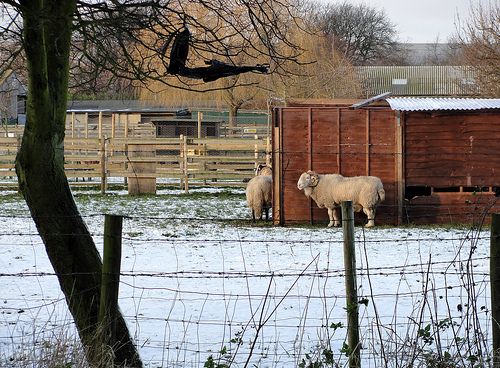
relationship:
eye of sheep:
[304, 175, 312, 180] [295, 166, 387, 229]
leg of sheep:
[360, 205, 377, 227] [295, 166, 387, 229]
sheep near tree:
[295, 166, 387, 229] [1, 0, 318, 365]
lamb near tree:
[246, 162, 277, 222] [1, 0, 318, 365]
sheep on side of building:
[295, 166, 387, 229] [275, 62, 498, 224]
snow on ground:
[0, 220, 500, 368] [4, 148, 497, 365]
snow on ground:
[14, 225, 461, 353] [4, 148, 497, 365]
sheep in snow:
[295, 166, 387, 229] [0, 220, 500, 368]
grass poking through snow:
[0, 178, 490, 253] [0, 220, 500, 368]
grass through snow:
[0, 178, 490, 253] [0, 220, 500, 368]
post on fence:
[322, 189, 381, 366] [3, 206, 499, 366]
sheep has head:
[295, 166, 387, 229] [284, 158, 322, 198]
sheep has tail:
[295, 170, 387, 229] [373, 178, 389, 207]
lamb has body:
[246, 162, 277, 222] [244, 173, 269, 209]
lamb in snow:
[246, 162, 277, 222] [0, 220, 500, 368]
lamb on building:
[246, 162, 277, 222] [275, 62, 498, 224]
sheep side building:
[295, 170, 387, 229] [253, 80, 498, 232]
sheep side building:
[243, 167, 275, 229] [253, 80, 498, 232]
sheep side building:
[295, 166, 387, 229] [275, 96, 497, 212]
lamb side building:
[246, 162, 277, 222] [275, 96, 497, 212]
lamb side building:
[246, 162, 277, 222] [261, 47, 499, 228]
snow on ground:
[0, 220, 500, 368] [181, 245, 330, 363]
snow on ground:
[0, 220, 500, 368] [362, 240, 489, 358]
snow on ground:
[0, 220, 500, 368] [132, 256, 232, 357]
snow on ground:
[0, 220, 500, 368] [124, 225, 340, 352]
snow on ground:
[0, 220, 500, 368] [1, 207, 488, 365]